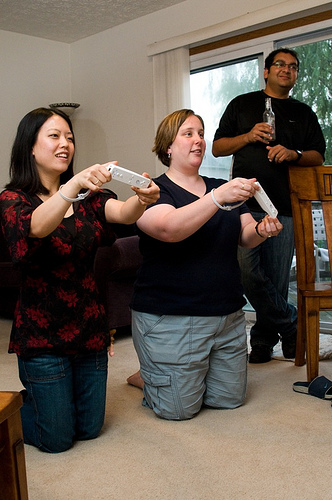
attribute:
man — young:
[222, 48, 327, 186]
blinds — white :
[151, 55, 191, 108]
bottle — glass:
[259, 94, 281, 143]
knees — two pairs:
[27, 387, 252, 453]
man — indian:
[203, 44, 330, 305]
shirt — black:
[9, 180, 153, 367]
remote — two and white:
[207, 177, 278, 220]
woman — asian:
[19, 121, 131, 310]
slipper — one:
[291, 372, 330, 400]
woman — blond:
[127, 109, 282, 419]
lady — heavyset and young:
[157, 161, 242, 362]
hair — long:
[27, 89, 61, 239]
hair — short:
[142, 113, 179, 178]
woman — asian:
[17, 208, 123, 413]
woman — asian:
[41, 238, 114, 390]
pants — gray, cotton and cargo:
[158, 328, 248, 434]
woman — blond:
[166, 244, 245, 384]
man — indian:
[259, 118, 309, 180]